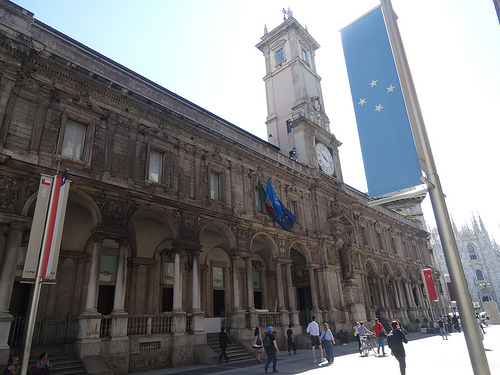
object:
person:
[216, 326, 232, 366]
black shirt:
[218, 332, 231, 346]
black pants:
[215, 341, 232, 365]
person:
[371, 317, 388, 355]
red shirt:
[371, 322, 386, 337]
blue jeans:
[374, 335, 386, 357]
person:
[306, 314, 328, 367]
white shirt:
[306, 321, 320, 337]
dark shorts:
[309, 333, 320, 347]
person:
[319, 321, 339, 366]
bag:
[319, 332, 327, 344]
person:
[261, 324, 283, 374]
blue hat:
[266, 327, 275, 332]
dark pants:
[263, 344, 277, 374]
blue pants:
[322, 339, 336, 365]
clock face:
[313, 142, 337, 177]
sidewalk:
[149, 315, 500, 375]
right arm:
[271, 335, 280, 351]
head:
[389, 320, 401, 331]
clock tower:
[250, 7, 348, 186]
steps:
[218, 351, 249, 358]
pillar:
[76, 236, 104, 339]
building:
[0, 0, 453, 375]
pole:
[379, 0, 492, 375]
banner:
[337, 4, 428, 205]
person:
[250, 324, 266, 365]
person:
[355, 321, 374, 356]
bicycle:
[357, 330, 383, 357]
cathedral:
[424, 210, 500, 326]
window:
[276, 48, 284, 64]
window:
[301, 47, 309, 61]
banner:
[419, 265, 441, 305]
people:
[384, 318, 411, 375]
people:
[437, 317, 449, 341]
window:
[59, 118, 88, 161]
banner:
[20, 172, 71, 287]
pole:
[19, 163, 64, 375]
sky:
[0, 0, 500, 242]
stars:
[372, 103, 386, 113]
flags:
[264, 174, 300, 231]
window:
[145, 143, 164, 185]